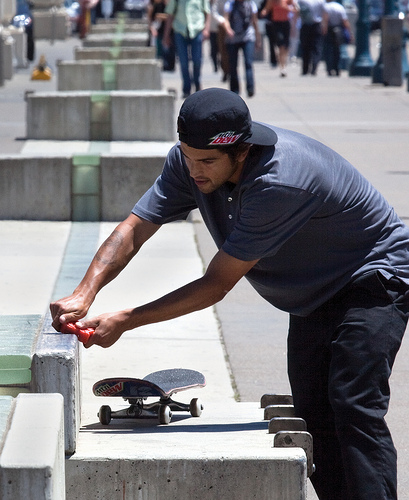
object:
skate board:
[92, 368, 206, 426]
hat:
[176, 87, 278, 150]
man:
[47, 86, 407, 499]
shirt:
[129, 121, 408, 318]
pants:
[285, 270, 407, 500]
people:
[165, 2, 211, 100]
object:
[59, 322, 94, 344]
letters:
[230, 135, 239, 142]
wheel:
[190, 398, 204, 417]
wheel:
[159, 404, 173, 425]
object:
[31, 54, 53, 80]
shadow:
[80, 421, 276, 435]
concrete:
[67, 399, 307, 498]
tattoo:
[93, 229, 123, 267]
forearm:
[73, 220, 136, 300]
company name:
[95, 382, 124, 397]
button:
[227, 197, 233, 202]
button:
[228, 214, 233, 219]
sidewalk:
[165, 44, 408, 497]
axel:
[110, 404, 159, 419]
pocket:
[370, 269, 399, 303]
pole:
[380, 13, 404, 88]